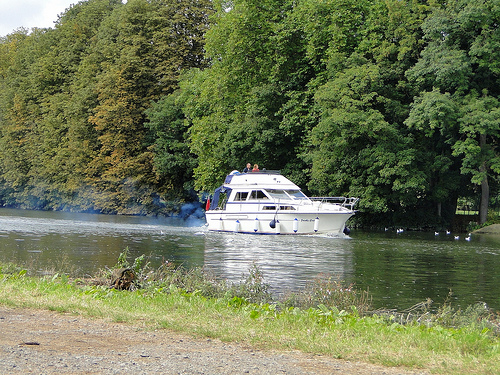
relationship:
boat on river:
[199, 172, 355, 240] [0, 205, 500, 312]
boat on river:
[202, 169, 360, 235] [0, 205, 499, 372]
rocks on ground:
[65, 326, 115, 350] [127, 308, 187, 357]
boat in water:
[202, 169, 360, 235] [342, 255, 402, 298]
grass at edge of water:
[132, 294, 220, 324] [355, 261, 444, 306]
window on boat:
[245, 179, 285, 209] [262, 194, 349, 244]